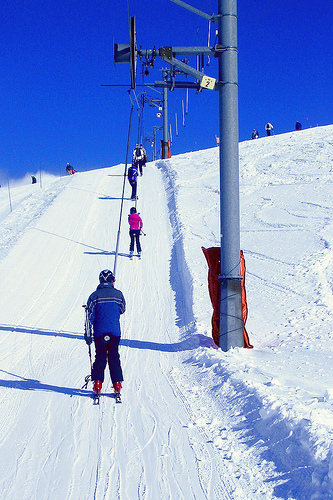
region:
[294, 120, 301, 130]
the person standing on the snow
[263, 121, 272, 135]
the person standing on the snow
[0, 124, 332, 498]
the snow on the ground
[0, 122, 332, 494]
the tracks on the snow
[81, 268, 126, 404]
the person going up the hill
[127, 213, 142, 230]
the pink long sleeved jacket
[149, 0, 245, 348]
the large poles in the snow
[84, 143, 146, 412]
the people going up the hill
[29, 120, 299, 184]
the people at the top of the hill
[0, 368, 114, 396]
the shadow on the snow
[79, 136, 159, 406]
skiers riding the saddle-style ski lift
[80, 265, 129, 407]
this type of ski lift looks very painful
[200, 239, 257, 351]
padding on the pole for skiers who are way off course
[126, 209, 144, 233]
this skier is wearing a lovely pink jacket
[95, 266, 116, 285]
this responsible skier is wearing a helmet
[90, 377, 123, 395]
this skier is wearing red ski boots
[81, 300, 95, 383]
this skier holds both ski poles in one hand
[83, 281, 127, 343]
this skier is wearing a blue ski jacket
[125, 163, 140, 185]
this skier is wearing a bright blue jacket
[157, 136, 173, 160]
more padding on a support strut up ahead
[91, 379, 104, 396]
red ski boots mounted to skis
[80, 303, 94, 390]
ski poles in the hands of a skier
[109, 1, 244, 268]
ski tow rope lift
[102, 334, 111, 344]
the ski tow rope peg seat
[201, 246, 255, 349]
an orange safety pad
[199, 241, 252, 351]
the ski lift tower safety pad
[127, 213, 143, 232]
a skier with a pink ski jacket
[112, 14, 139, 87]
the ski lift pulley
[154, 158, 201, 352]
a snow bank on the lift trail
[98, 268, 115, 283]
a knit cap on the skier